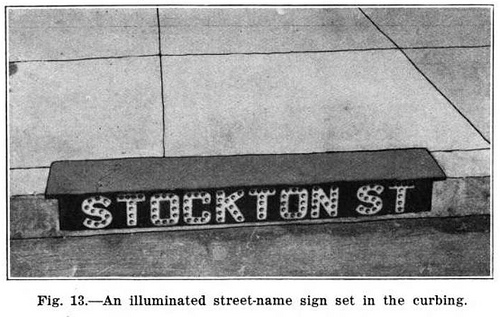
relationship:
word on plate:
[83, 182, 417, 229] [46, 147, 444, 233]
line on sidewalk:
[8, 43, 490, 65] [10, 5, 492, 241]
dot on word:
[98, 207, 107, 215] [83, 182, 417, 229]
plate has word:
[46, 147, 444, 233] [83, 182, 417, 229]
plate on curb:
[46, 147, 444, 233] [9, 148, 494, 239]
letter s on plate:
[81, 194, 113, 230] [46, 147, 444, 233]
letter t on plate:
[118, 189, 145, 227] [46, 147, 444, 233]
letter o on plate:
[149, 190, 182, 228] [46, 147, 444, 233]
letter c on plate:
[183, 189, 214, 225] [46, 147, 444, 233]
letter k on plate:
[215, 186, 246, 225] [46, 147, 444, 233]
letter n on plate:
[310, 183, 339, 219] [46, 147, 444, 233]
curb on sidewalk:
[9, 148, 494, 239] [10, 5, 492, 241]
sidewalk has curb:
[10, 5, 492, 241] [9, 148, 494, 239]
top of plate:
[44, 147, 446, 199] [46, 147, 444, 233]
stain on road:
[165, 213, 491, 244] [10, 212, 490, 279]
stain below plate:
[165, 213, 491, 244] [46, 147, 444, 233]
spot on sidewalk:
[273, 5, 293, 16] [10, 5, 492, 241]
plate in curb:
[46, 147, 444, 233] [9, 148, 494, 239]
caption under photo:
[37, 291, 468, 309] [6, 2, 496, 281]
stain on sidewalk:
[7, 60, 19, 76] [10, 5, 492, 241]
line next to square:
[8, 43, 490, 65] [159, 46, 491, 159]